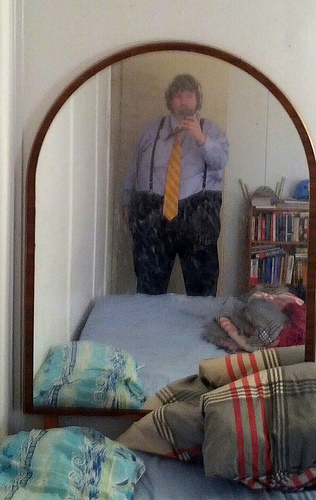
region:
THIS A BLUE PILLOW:
[31, 339, 149, 410]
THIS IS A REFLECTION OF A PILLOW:
[0, 424, 148, 499]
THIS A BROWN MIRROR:
[22, 38, 314, 424]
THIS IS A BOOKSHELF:
[242, 175, 312, 299]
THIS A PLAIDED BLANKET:
[115, 345, 314, 498]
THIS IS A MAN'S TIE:
[161, 124, 186, 219]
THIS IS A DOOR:
[112, 47, 228, 294]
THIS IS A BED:
[55, 293, 314, 498]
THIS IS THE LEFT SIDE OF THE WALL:
[0, 0, 109, 427]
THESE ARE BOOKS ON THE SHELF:
[250, 210, 309, 294]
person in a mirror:
[117, 66, 228, 297]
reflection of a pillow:
[29, 330, 146, 410]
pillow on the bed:
[1, 415, 147, 498]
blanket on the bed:
[100, 355, 313, 496]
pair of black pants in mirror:
[121, 187, 227, 300]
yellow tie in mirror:
[159, 129, 186, 222]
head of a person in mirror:
[163, 69, 206, 118]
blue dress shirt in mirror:
[115, 112, 231, 212]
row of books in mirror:
[249, 205, 311, 242]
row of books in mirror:
[249, 243, 309, 285]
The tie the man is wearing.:
[162, 131, 178, 219]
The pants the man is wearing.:
[136, 195, 222, 297]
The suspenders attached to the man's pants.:
[143, 115, 207, 194]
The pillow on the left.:
[2, 423, 141, 498]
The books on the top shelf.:
[250, 213, 306, 240]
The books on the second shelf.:
[251, 246, 303, 283]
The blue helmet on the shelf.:
[297, 180, 312, 199]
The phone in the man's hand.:
[183, 108, 192, 121]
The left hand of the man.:
[122, 206, 128, 224]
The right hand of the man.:
[185, 118, 202, 141]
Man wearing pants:
[126, 187, 220, 298]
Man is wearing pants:
[128, 187, 221, 298]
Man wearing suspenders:
[146, 111, 209, 196]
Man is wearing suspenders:
[147, 111, 209, 198]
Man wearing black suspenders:
[145, 112, 208, 196]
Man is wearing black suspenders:
[147, 112, 209, 199]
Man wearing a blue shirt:
[122, 111, 226, 207]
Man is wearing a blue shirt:
[119, 111, 230, 207]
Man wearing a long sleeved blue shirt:
[120, 110, 227, 212]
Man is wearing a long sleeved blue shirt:
[118, 108, 229, 208]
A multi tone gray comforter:
[115, 361, 314, 490]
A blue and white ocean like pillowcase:
[0, 426, 145, 498]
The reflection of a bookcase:
[246, 199, 309, 295]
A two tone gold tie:
[162, 128, 184, 221]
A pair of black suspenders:
[147, 115, 207, 195]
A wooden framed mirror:
[24, 39, 311, 429]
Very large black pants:
[130, 189, 222, 298]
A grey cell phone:
[182, 108, 194, 131]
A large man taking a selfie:
[122, 73, 228, 296]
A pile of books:
[251, 243, 286, 256]